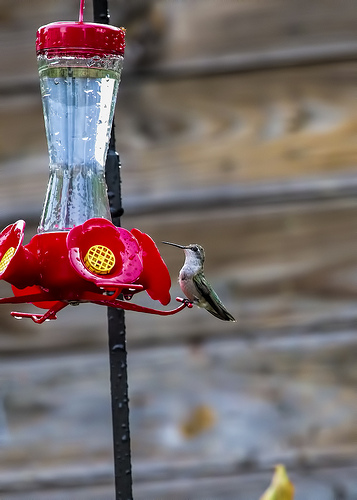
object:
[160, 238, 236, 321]
bird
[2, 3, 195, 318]
feeder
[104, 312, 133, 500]
pole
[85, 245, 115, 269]
middle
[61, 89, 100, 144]
water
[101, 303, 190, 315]
perch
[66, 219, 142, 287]
shape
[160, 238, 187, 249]
beak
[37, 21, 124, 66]
cap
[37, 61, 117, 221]
glass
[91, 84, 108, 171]
reflection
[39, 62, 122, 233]
plastic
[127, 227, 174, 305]
feeding station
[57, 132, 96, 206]
food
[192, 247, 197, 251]
eye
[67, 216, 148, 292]
flower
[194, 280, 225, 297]
wings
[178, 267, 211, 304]
body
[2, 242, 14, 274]
food dispenser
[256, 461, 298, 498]
bird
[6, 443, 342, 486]
ground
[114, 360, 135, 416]
water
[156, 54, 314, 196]
wall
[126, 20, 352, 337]
background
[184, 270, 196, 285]
feathers